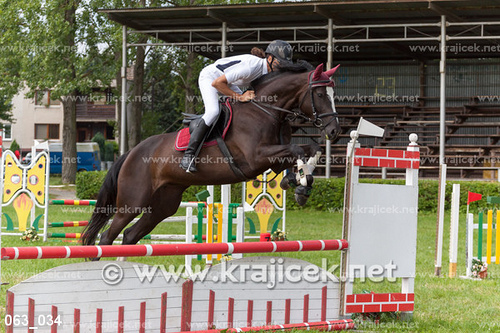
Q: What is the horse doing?
A: Jumping.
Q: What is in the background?
A: Trees.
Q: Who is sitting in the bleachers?
A: No one is there.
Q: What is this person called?
A: A jockey.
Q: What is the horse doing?
A: Jumping.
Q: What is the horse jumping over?
A: Obstacle.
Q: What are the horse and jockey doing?
A: Practicing.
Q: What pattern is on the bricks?
A: Striped.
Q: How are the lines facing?
A: Vertical.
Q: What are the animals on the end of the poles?
A: Butterflies.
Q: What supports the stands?
A: Metal poles.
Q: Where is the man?
A: On the horse.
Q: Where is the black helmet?
A: On the man's head.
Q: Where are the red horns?
A: The horse's head.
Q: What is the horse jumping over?
A: A red jumping bar.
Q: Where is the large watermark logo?
A: Toward the bottom.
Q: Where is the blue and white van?
A: Behind the tree.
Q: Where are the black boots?
A: On the jockey.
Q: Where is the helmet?
A: The jockey's head.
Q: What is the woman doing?
A: Riding a horse.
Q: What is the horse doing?
A: Jumping.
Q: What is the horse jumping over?
A: An obstacle.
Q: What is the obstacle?
A: A pole.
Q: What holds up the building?
A: Metal posts.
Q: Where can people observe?
A: The bleachers.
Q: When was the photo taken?
A: Daytime.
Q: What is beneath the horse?
A: A stand.